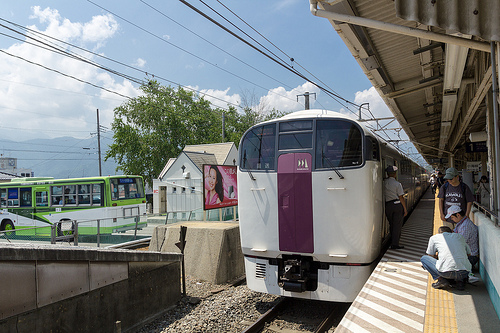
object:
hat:
[444, 204, 462, 219]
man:
[444, 205, 481, 268]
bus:
[0, 175, 148, 242]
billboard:
[203, 162, 238, 209]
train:
[238, 107, 427, 313]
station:
[207, 0, 496, 332]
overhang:
[320, 0, 500, 175]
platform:
[330, 171, 498, 332]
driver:
[383, 166, 408, 250]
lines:
[1, 1, 271, 77]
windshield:
[241, 120, 363, 172]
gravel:
[186, 305, 234, 332]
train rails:
[244, 297, 340, 332]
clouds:
[1, 15, 408, 164]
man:
[437, 168, 475, 231]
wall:
[477, 213, 500, 308]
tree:
[107, 79, 278, 189]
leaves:
[115, 85, 265, 180]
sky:
[1, 3, 431, 200]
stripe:
[424, 175, 459, 333]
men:
[420, 226, 473, 291]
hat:
[443, 167, 458, 179]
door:
[277, 152, 314, 253]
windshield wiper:
[242, 154, 345, 181]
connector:
[279, 258, 313, 293]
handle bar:
[251, 247, 268, 252]